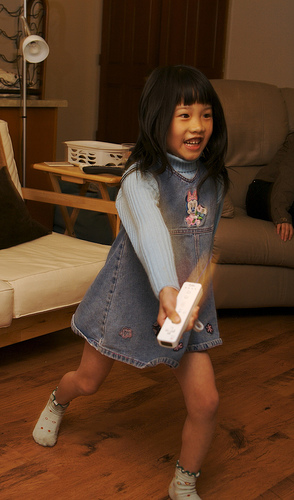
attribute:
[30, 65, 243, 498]
girl — forward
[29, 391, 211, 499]
socks — white, speckled, frilly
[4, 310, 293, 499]
floor — wood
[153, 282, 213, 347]
remote — white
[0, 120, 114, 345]
seat — white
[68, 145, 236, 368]
dress — blue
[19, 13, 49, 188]
lamp — white, tall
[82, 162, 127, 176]
remote — black, plastic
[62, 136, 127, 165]
basket — white, plastic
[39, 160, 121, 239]
table — wood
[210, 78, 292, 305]
sofa — beige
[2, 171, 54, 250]
pillow — black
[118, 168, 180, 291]
girl sweater — blue